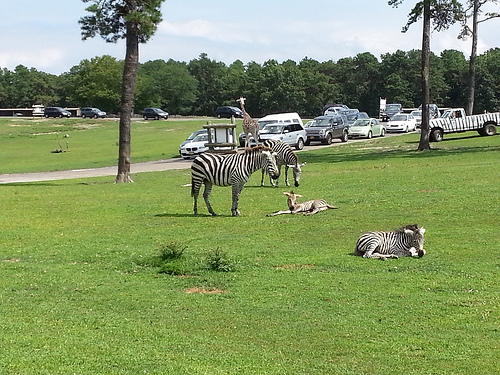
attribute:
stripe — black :
[218, 159, 229, 184]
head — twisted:
[233, 89, 245, 109]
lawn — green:
[372, 313, 445, 374]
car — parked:
[346, 116, 387, 138]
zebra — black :
[168, 143, 288, 188]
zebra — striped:
[348, 216, 438, 268]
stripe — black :
[197, 152, 213, 180]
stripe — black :
[357, 234, 369, 251]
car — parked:
[286, 115, 363, 156]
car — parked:
[179, 133, 237, 159]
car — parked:
[262, 122, 308, 151]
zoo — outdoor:
[1, 109, 498, 371]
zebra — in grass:
[195, 154, 284, 207]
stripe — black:
[210, 149, 226, 166]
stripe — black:
[190, 154, 206, 183]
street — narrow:
[4, 109, 456, 185]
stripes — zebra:
[426, 113, 496, 134]